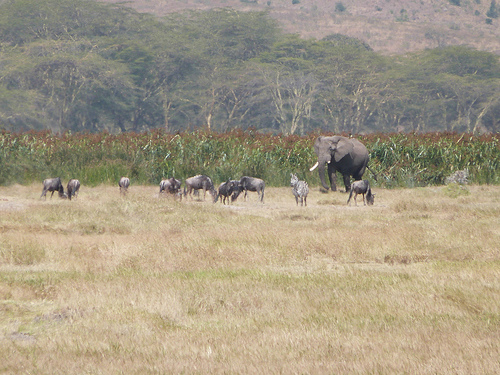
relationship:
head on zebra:
[288, 172, 298, 187] [288, 170, 310, 207]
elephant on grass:
[308, 134, 376, 192] [276, 213, 461, 373]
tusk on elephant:
[309, 160, 331, 172] [304, 129, 373, 198]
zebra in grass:
[287, 170, 310, 204] [1, 174, 499, 370]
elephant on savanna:
[315, 135, 369, 192] [1, 1, 497, 372]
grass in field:
[1, 174, 499, 370] [8, 185, 498, 364]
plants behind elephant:
[0, 128, 484, 182] [309, 134, 373, 200]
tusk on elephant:
[309, 160, 329, 172] [312, 136, 377, 190]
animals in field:
[29, 129, 435, 233] [2, 122, 498, 369]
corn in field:
[88, 137, 173, 159] [19, 44, 479, 284]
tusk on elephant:
[309, 160, 331, 172] [307, 133, 377, 194]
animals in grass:
[37, 135, 376, 209] [6, 180, 465, 365]